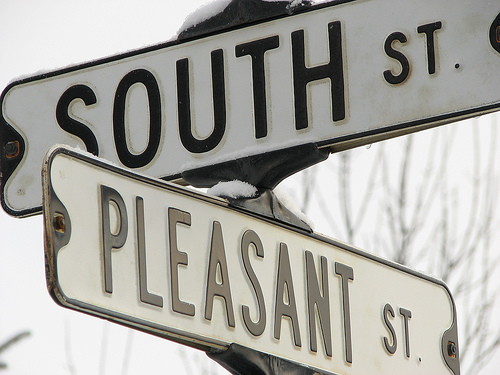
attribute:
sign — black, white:
[2, 4, 495, 194]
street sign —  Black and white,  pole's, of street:
[18, 54, 468, 363]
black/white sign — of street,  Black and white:
[13, 6, 492, 370]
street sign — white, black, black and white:
[1, 1, 499, 218]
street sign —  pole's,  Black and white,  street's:
[42, 142, 461, 373]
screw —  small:
[48, 209, 70, 240]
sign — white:
[48, 169, 461, 374]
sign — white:
[1, 0, 498, 210]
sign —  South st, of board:
[44, 142, 462, 372]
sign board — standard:
[1, 0, 498, 220]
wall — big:
[2, 4, 498, 373]